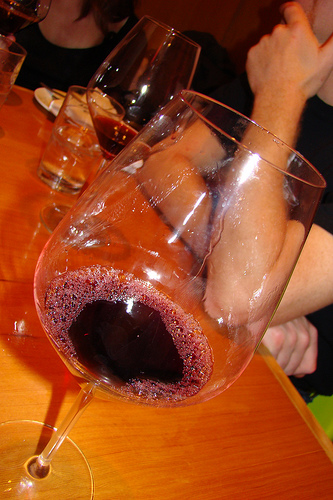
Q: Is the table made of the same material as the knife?
A: No, the table is made of wood and the knife is made of metal.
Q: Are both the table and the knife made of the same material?
A: No, the table is made of wood and the knife is made of metal.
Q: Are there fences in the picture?
A: No, there are no fences.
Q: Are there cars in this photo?
A: No, there are no cars.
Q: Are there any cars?
A: No, there are no cars.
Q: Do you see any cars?
A: No, there are no cars.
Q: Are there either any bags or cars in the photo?
A: No, there are no cars or bags.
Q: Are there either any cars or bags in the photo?
A: No, there are no cars or bags.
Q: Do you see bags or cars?
A: No, there are no cars or bags.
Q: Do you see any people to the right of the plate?
A: Yes, there is a person to the right of the plate.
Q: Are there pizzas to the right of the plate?
A: No, there is a person to the right of the plate.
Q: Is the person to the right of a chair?
A: No, the person is to the right of the plate.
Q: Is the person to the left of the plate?
A: No, the person is to the right of the plate.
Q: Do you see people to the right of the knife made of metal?
A: Yes, there is a person to the right of the knife.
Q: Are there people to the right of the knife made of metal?
A: Yes, there is a person to the right of the knife.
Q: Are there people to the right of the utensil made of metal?
A: Yes, there is a person to the right of the knife.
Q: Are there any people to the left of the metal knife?
A: No, the person is to the right of the knife.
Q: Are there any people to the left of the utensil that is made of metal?
A: No, the person is to the right of the knife.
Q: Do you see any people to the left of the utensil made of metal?
A: No, the person is to the right of the knife.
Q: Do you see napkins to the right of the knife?
A: No, there is a person to the right of the knife.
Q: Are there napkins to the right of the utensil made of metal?
A: No, there is a person to the right of the knife.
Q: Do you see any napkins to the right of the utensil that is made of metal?
A: No, there is a person to the right of the knife.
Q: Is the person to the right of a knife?
A: Yes, the person is to the right of a knife.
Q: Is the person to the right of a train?
A: No, the person is to the right of a knife.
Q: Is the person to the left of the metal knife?
A: No, the person is to the right of the knife.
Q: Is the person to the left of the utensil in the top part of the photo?
A: No, the person is to the right of the knife.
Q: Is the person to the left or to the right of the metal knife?
A: The person is to the right of the knife.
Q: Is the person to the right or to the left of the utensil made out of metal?
A: The person is to the right of the knife.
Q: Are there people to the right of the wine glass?
A: Yes, there is a person to the right of the wine glass.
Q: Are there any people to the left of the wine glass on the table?
A: No, the person is to the right of the wineglass.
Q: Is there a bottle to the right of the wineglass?
A: No, there is a person to the right of the wineglass.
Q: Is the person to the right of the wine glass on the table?
A: Yes, the person is to the right of the wine glass.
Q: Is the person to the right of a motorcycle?
A: No, the person is to the right of the wine glass.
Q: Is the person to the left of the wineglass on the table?
A: No, the person is to the right of the wineglass.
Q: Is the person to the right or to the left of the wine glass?
A: The person is to the right of the wine glass.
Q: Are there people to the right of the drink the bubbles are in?
A: Yes, there is a person to the right of the wine.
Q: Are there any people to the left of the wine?
A: No, the person is to the right of the wine.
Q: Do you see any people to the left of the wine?
A: No, the person is to the right of the wine.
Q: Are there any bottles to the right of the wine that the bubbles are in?
A: No, there is a person to the right of the wine.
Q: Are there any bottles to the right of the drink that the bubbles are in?
A: No, there is a person to the right of the wine.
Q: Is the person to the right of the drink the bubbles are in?
A: Yes, the person is to the right of the wine.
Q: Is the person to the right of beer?
A: No, the person is to the right of the wine.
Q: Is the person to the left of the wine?
A: No, the person is to the right of the wine.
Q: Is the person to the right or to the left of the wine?
A: The person is to the right of the wine.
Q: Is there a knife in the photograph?
A: Yes, there is a knife.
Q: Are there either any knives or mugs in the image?
A: Yes, there is a knife.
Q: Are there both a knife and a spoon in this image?
A: No, there is a knife but no spoons.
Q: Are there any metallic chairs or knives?
A: Yes, there is a metal knife.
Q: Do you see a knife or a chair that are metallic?
A: Yes, the knife is metallic.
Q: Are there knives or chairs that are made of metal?
A: Yes, the knife is made of metal.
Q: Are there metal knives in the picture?
A: Yes, there is a metal knife.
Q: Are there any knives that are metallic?
A: Yes, there is a knife that is metallic.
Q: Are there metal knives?
A: Yes, there is a knife that is made of metal.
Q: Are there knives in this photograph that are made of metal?
A: Yes, there is a knife that is made of metal.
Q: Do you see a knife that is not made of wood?
A: Yes, there is a knife that is made of metal.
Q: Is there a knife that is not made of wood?
A: Yes, there is a knife that is made of metal.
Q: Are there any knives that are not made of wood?
A: Yes, there is a knife that is made of metal.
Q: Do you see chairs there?
A: No, there are no chairs.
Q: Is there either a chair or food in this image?
A: No, there are no chairs or food.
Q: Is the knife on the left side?
A: Yes, the knife is on the left of the image.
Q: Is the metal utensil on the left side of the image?
A: Yes, the knife is on the left of the image.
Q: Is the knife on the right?
A: No, the knife is on the left of the image.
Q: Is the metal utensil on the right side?
A: No, the knife is on the left of the image.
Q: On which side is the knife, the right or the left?
A: The knife is on the left of the image.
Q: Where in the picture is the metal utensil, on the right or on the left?
A: The knife is on the left of the image.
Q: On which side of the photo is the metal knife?
A: The knife is on the left of the image.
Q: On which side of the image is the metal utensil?
A: The knife is on the left of the image.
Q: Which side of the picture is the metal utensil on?
A: The knife is on the left of the image.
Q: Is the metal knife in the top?
A: Yes, the knife is in the top of the image.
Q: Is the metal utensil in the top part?
A: Yes, the knife is in the top of the image.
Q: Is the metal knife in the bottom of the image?
A: No, the knife is in the top of the image.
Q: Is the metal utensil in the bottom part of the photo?
A: No, the knife is in the top of the image.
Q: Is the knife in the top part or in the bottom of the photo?
A: The knife is in the top of the image.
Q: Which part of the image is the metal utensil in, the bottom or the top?
A: The knife is in the top of the image.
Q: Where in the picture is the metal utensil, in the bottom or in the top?
A: The knife is in the top of the image.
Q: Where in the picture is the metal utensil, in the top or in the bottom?
A: The knife is in the top of the image.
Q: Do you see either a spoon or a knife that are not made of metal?
A: No, there is a knife but it is made of metal.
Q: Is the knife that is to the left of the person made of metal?
A: Yes, the knife is made of metal.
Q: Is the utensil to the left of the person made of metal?
A: Yes, the knife is made of metal.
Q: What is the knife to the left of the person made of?
A: The knife is made of metal.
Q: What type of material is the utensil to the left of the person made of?
A: The knife is made of metal.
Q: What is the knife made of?
A: The knife is made of metal.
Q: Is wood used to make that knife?
A: No, the knife is made of metal.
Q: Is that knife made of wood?
A: No, the knife is made of metal.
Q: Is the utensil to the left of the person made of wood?
A: No, the knife is made of metal.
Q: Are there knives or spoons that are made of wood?
A: No, there is a knife but it is made of metal.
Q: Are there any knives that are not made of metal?
A: No, there is a knife but it is made of metal.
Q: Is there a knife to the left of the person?
A: Yes, there is a knife to the left of the person.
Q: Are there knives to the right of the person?
A: No, the knife is to the left of the person.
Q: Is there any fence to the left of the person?
A: No, there is a knife to the left of the person.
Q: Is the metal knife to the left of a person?
A: Yes, the knife is to the left of a person.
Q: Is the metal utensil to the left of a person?
A: Yes, the knife is to the left of a person.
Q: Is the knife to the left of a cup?
A: No, the knife is to the left of a person.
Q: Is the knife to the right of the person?
A: No, the knife is to the left of the person.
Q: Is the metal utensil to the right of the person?
A: No, the knife is to the left of the person.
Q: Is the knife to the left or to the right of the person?
A: The knife is to the left of the person.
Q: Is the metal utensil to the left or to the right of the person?
A: The knife is to the left of the person.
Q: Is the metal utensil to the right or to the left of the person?
A: The knife is to the left of the person.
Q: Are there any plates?
A: Yes, there is a plate.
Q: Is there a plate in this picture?
A: Yes, there is a plate.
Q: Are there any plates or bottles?
A: Yes, there is a plate.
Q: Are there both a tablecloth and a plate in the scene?
A: No, there is a plate but no tablecloths.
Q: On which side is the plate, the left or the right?
A: The plate is on the left of the image.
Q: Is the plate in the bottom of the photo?
A: No, the plate is in the top of the image.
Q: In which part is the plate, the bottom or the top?
A: The plate is in the top of the image.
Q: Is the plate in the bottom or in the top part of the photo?
A: The plate is in the top of the image.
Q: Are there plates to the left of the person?
A: Yes, there is a plate to the left of the person.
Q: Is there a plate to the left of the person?
A: Yes, there is a plate to the left of the person.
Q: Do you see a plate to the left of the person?
A: Yes, there is a plate to the left of the person.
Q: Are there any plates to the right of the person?
A: No, the plate is to the left of the person.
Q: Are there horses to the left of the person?
A: No, there is a plate to the left of the person.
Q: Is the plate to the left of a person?
A: Yes, the plate is to the left of a person.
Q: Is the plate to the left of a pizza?
A: No, the plate is to the left of a person.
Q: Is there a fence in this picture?
A: No, there are no fences.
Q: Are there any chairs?
A: No, there are no chairs.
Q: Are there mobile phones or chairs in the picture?
A: No, there are no chairs or mobile phones.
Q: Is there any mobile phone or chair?
A: No, there are no chairs or cell phones.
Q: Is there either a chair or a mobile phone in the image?
A: No, there are no chairs or cell phones.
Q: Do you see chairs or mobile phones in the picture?
A: No, there are no chairs or mobile phones.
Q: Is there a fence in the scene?
A: No, there are no fences.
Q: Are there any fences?
A: No, there are no fences.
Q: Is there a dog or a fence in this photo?
A: No, there are no fences or dogs.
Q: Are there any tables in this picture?
A: Yes, there is a table.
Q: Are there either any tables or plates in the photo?
A: Yes, there is a table.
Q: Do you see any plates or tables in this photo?
A: Yes, there is a table.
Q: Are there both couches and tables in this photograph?
A: No, there is a table but no couches.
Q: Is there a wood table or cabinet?
A: Yes, there is a wood table.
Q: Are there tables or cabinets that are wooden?
A: Yes, the table is wooden.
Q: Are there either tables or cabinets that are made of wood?
A: Yes, the table is made of wood.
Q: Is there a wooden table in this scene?
A: Yes, there is a wood table.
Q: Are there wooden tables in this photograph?
A: Yes, there is a wood table.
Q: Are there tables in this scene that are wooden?
A: Yes, there is a table that is wooden.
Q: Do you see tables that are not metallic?
A: Yes, there is a wooden table.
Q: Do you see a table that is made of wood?
A: Yes, there is a table that is made of wood.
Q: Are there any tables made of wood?
A: Yes, there is a table that is made of wood.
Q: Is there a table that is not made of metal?
A: Yes, there is a table that is made of wood.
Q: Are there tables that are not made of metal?
A: Yes, there is a table that is made of wood.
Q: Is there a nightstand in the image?
A: No, there are no nightstands.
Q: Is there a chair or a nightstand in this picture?
A: No, there are no nightstands or chairs.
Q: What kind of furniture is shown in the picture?
A: The furniture is a table.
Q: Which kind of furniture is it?
A: The piece of furniture is a table.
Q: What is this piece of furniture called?
A: This is a table.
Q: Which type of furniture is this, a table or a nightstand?
A: This is a table.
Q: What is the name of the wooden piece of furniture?
A: The piece of furniture is a table.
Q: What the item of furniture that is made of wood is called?
A: The piece of furniture is a table.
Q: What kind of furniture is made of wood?
A: The furniture is a table.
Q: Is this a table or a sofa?
A: This is a table.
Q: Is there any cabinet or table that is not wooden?
A: No, there is a table but it is wooden.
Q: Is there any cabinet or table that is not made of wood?
A: No, there is a table but it is made of wood.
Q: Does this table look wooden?
A: Yes, the table is wooden.